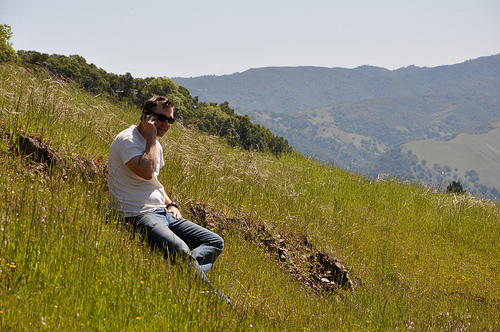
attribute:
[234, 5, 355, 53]
sky — blue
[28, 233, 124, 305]
grass — green